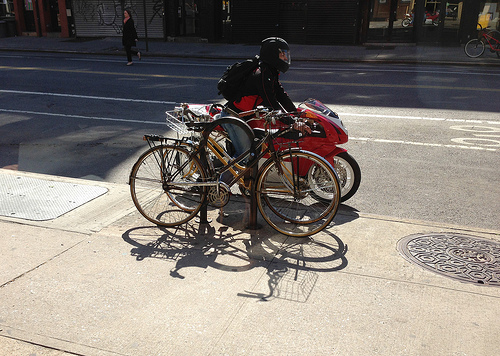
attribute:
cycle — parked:
[128, 106, 365, 200]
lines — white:
[1, 84, 498, 156]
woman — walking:
[117, 7, 137, 68]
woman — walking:
[112, 7, 149, 67]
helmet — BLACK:
[244, 36, 296, 66]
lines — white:
[1, 88, 498, 125]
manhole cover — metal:
[403, 230, 499, 291]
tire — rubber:
[257, 150, 346, 237]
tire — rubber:
[121, 136, 212, 233]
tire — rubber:
[334, 146, 370, 207]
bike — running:
[100, 102, 353, 223]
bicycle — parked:
[129, 117, 341, 237]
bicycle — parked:
[163, 112, 345, 223]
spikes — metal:
[118, 149, 198, 214]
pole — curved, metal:
[199, 116, 259, 231]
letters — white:
[438, 115, 497, 158]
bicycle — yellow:
[130, 114, 335, 225]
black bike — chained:
[131, 124, 338, 241]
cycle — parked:
[127, 102, 341, 244]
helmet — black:
[246, 26, 300, 76]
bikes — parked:
[127, 94, 363, 236]